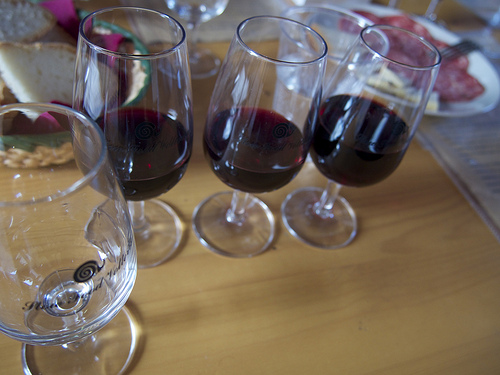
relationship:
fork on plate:
[435, 37, 483, 65] [286, 4, 497, 118]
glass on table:
[73, 6, 195, 268] [0, 0, 499, 374]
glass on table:
[0, 103, 138, 374] [159, 234, 471, 374]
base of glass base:
[281, 186, 357, 248] [282, 185, 358, 250]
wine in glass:
[203, 107, 310, 195] [191, 14, 328, 258]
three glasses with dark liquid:
[87, 21, 447, 198] [117, 120, 200, 185]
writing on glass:
[6, 212, 143, 323] [8, 70, 151, 373]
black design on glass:
[69, 257, 107, 285] [0, 100, 144, 374]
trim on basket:
[0, 10, 155, 150] [0, 9, 150, 166]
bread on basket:
[0, 40, 121, 123] [0, 9, 150, 166]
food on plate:
[336, 7, 484, 109] [286, 4, 497, 118]